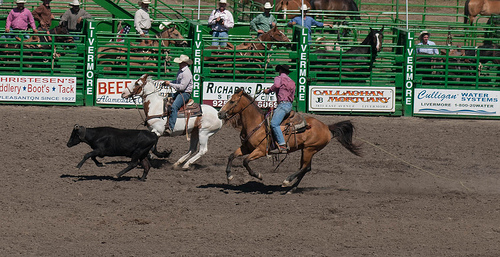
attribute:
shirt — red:
[268, 69, 308, 100]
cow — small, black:
[64, 113, 155, 176]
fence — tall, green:
[149, 1, 377, 91]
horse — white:
[106, 61, 208, 170]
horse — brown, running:
[222, 90, 347, 180]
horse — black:
[324, 31, 392, 91]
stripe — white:
[362, 22, 381, 51]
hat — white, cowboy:
[165, 51, 217, 80]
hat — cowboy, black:
[276, 61, 318, 79]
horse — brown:
[213, 88, 363, 198]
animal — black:
[64, 130, 174, 183]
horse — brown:
[219, 87, 354, 193]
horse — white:
[122, 74, 225, 169]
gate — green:
[303, 4, 414, 110]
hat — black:
[273, 62, 289, 71]